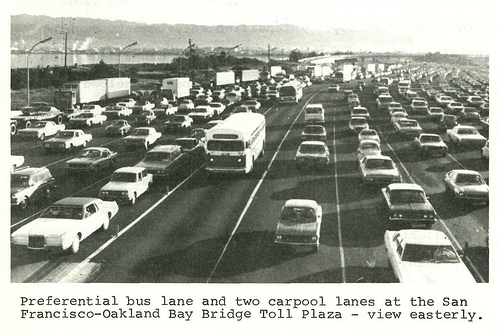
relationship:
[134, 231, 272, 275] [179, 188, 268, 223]
shadow on ground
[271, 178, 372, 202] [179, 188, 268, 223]
shadow on ground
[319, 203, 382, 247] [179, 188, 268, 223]
shadow on ground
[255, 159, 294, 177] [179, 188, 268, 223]
shadow on ground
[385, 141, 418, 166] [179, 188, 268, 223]
shadow on ground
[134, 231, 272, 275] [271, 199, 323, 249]
shadow of car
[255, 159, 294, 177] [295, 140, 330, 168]
shadow of car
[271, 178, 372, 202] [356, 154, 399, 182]
shadow of car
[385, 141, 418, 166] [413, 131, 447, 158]
shadow of car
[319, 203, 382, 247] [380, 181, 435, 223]
shadow of car